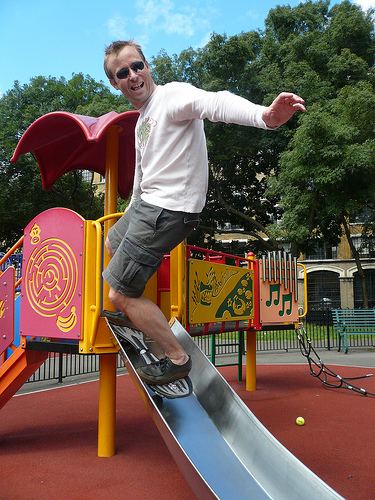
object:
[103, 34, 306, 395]
man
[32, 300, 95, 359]
slide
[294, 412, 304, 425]
tennis ball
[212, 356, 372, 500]
ground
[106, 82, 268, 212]
sweater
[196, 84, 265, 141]
sleeve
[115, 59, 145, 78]
sunglasses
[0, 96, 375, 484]
playground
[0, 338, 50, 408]
stairs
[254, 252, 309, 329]
board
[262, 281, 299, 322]
musical notes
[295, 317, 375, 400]
ladder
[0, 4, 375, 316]
trees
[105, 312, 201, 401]
skateboard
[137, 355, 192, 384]
shoe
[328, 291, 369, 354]
bench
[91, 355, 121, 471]
pole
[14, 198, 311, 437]
jungle gym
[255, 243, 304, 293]
instruments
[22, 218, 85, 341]
maze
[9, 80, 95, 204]
bush